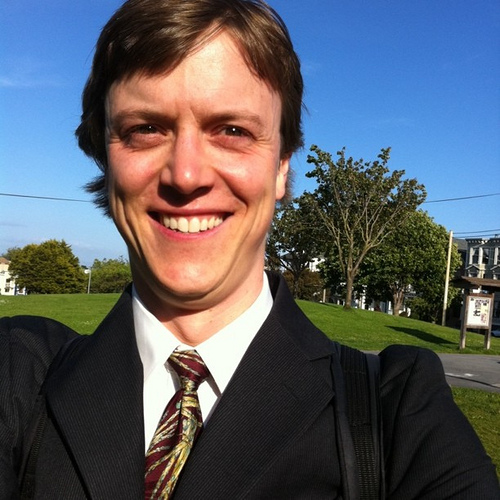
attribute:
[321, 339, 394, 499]
strap — here, one, black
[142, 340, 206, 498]
tie — burgandy, red, gold, colored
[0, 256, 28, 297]
building — back, grey, apartment, white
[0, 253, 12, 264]
roof — brown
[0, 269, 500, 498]
jacket — black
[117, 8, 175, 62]
hair — brown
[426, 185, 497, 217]
line — power, black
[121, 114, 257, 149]
eyes — brown, squinting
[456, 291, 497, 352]
sign — brown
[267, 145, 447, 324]
trees — tall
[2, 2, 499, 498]
guy — young, here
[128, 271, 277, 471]
shirt — white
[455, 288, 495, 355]
sign — wooden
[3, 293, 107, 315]
grass — green